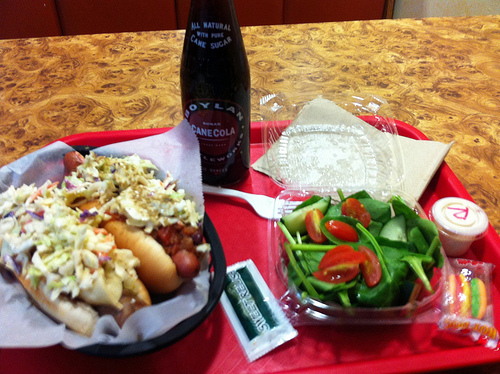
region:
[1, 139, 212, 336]
two hot dogs with lots of delicious toppings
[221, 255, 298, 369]
a pack of relish on the red tray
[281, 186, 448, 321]
green salad with wedges of tomato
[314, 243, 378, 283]
red tomato wedges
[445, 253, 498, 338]
a small pack of gummy candy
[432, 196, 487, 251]
a small container of white sauce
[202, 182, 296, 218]
white plastic fork on the red tray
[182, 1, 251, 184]
a bottle of cane soda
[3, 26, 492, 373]
a red tray of food and drink on a brown table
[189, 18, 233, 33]
white text on the soda bottle reading All Natural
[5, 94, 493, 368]
A TRAY OF FOOD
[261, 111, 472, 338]
A SMALL SIDE SALAD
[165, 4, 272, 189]
A BOTTLE OF POP ON A TRAY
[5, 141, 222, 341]
TWO HOT DOGS WITH SLAW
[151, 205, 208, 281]
CHILI ON A HOT DOG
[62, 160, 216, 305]
A WHITE HOT DOG BUN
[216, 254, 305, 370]
A PACKET OF DRESSING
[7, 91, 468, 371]
A RED TRAY ON THE TABLE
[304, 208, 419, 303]
TOMATOES AND SPINACH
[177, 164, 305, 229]
A WHITE PLASTIC FORK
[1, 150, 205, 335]
a pair of two hot dogs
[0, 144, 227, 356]
a black, plastic basket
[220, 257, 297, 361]
a small packet of sweetener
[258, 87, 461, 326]
a plastic container filled with salad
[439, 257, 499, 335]
a plastic bag with candy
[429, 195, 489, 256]
a small container of ranch dressing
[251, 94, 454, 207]
a paper napkin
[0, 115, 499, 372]
a red plastic tray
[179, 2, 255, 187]
a bottle of cola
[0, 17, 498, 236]
a brown table top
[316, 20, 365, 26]
edge of a table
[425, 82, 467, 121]
part of a table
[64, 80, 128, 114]
part of a dinner table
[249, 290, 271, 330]
sachet of sauce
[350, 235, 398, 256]
part of green vegetables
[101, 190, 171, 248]
portion of a hot dog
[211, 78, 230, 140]
part of a bottle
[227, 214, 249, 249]
a red food tray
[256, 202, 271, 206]
section of a white fork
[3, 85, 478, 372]
the food is on the tray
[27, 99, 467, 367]
the tray is red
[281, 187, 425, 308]
the salad is green and red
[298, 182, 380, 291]
the tomatoes are red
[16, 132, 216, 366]
two hot dogs in a basket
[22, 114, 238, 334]
the basket is black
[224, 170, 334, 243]
the fork is white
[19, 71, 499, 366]
the tray is on the table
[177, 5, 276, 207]
the soda is in the bottle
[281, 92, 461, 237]
the napkin is brown